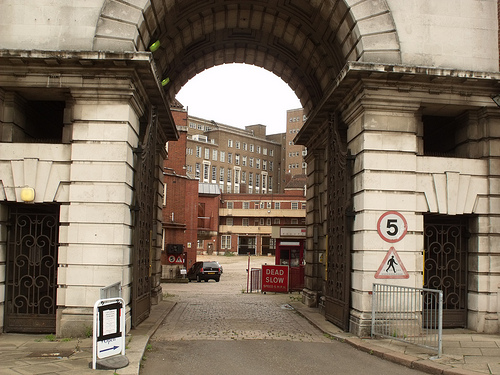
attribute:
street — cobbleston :
[137, 255, 446, 374]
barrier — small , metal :
[365, 279, 450, 374]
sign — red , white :
[262, 257, 291, 293]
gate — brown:
[92, 120, 182, 310]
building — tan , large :
[158, 111, 309, 196]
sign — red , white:
[261, 265, 288, 292]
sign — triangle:
[370, 243, 413, 283]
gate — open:
[142, 96, 357, 329]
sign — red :
[258, 262, 293, 299]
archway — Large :
[48, 2, 428, 347]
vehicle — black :
[181, 252, 231, 286]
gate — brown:
[3, 202, 59, 337]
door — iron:
[425, 212, 466, 327]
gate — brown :
[406, 232, 467, 278]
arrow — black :
[94, 339, 129, 361]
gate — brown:
[326, 113, 352, 331]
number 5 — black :
[386, 217, 401, 238]